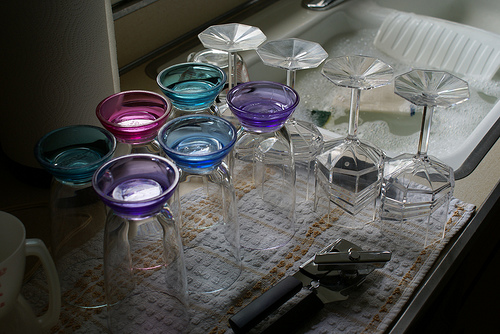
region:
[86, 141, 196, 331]
color base of drinking glass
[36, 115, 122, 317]
color base of drinking glass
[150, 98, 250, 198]
color base of drinking glass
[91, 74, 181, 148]
color base of drinking glass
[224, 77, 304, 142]
color base of drinking glass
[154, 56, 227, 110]
color base of drinking glass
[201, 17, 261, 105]
clear glass wine glass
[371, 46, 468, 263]
clear glass wine glass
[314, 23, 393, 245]
clear glass wine glass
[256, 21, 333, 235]
clear glass wine glass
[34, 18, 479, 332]
glasses and cups over a counter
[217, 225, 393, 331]
a can opener on a counter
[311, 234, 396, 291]
the blade of can opener is silver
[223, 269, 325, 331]
the handle of can opener is black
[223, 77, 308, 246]
base of glass is purple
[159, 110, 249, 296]
base of glass is blue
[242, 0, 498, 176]
a sink with water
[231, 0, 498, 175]
water in sink is foamy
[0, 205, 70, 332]
a cup with white handle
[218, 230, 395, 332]
a can opener over the sink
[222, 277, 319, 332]
black can opener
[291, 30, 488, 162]
water of sink is foamy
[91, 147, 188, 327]
a glass with purple base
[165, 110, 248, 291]
a glass with blue base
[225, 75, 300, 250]
a glass with purple base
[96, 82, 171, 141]
a glass with pink base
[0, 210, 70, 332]
white cup with handle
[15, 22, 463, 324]
glasses and cups on counter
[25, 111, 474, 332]
a towel on the counter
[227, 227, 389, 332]
a can opener on the towel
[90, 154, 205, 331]
a glass with a purple base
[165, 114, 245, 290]
a glass with a blue base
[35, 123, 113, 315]
a glass with a green vase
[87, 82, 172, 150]
a glass with a pink base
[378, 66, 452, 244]
a piece of stemware on the towel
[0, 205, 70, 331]
a measuring cup on the towel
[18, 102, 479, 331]
the towel is white and brown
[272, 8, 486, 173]
water in the sink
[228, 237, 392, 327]
Can opener with black handle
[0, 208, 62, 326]
White coffee mug in corner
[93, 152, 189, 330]
Glass with purple base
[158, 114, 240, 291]
Glass with blue base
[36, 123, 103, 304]
Glass with green base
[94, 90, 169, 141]
Pink base of upside down glass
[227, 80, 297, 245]
Upside down glass on kitchen counter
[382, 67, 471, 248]
Upside down wine glass on kitchen counter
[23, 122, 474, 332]
White towel under glasses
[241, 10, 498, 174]
Kitchen sink full of water